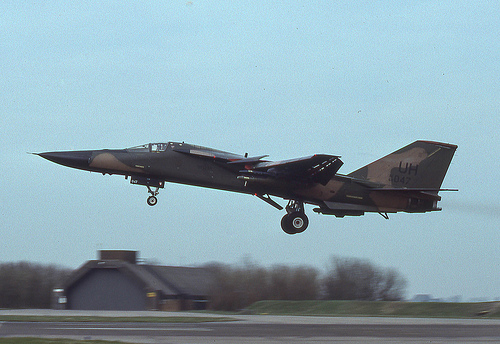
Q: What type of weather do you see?
A: It is clear.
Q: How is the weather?
A: It is clear.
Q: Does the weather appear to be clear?
A: Yes, it is clear.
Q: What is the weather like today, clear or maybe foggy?
A: It is clear.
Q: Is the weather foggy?
A: No, it is clear.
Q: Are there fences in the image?
A: No, there are no fences.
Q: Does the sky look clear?
A: Yes, the sky is clear.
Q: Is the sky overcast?
A: No, the sky is clear.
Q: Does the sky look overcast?
A: No, the sky is clear.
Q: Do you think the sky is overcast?
A: No, the sky is clear.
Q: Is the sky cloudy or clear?
A: The sky is clear.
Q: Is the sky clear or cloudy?
A: The sky is clear.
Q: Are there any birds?
A: No, there are no birds.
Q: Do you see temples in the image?
A: No, there are no temples.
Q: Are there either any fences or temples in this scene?
A: No, there are no temples or fences.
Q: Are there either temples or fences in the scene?
A: No, there are no temples or fences.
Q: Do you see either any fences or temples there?
A: No, there are no temples or fences.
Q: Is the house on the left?
A: Yes, the house is on the left of the image.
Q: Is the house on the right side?
A: No, the house is on the left of the image.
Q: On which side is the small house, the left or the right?
A: The house is on the left of the image.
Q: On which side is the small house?
A: The house is on the left of the image.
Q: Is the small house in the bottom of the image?
A: Yes, the house is in the bottom of the image.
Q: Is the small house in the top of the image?
A: No, the house is in the bottom of the image.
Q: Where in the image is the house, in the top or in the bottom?
A: The house is in the bottom of the image.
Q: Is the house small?
A: Yes, the house is small.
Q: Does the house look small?
A: Yes, the house is small.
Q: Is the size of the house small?
A: Yes, the house is small.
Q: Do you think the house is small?
A: Yes, the house is small.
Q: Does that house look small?
A: Yes, the house is small.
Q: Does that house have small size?
A: Yes, the house is small.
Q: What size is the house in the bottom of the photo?
A: The house is small.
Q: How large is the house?
A: The house is small.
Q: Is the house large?
A: No, the house is small.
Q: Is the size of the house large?
A: No, the house is small.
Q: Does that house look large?
A: No, the house is small.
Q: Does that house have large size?
A: No, the house is small.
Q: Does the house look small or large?
A: The house is small.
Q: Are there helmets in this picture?
A: No, there are no helmets.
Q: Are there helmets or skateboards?
A: No, there are no helmets or skateboards.